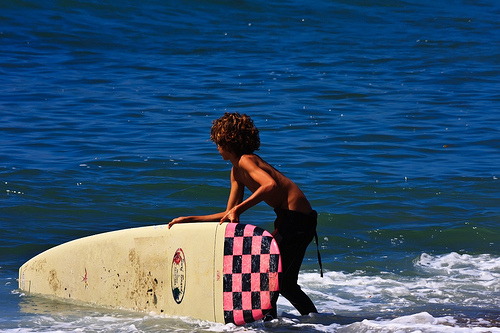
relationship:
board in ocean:
[18, 221, 285, 326] [0, 0, 500, 332]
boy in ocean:
[165, 111, 319, 325] [0, 0, 500, 332]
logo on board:
[168, 246, 187, 305] [18, 221, 285, 326]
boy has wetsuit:
[165, 111, 319, 325] [231, 151, 321, 309]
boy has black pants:
[165, 111, 319, 325] [264, 209, 326, 321]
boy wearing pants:
[165, 111, 319, 325] [259, 202, 322, 312]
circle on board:
[156, 247, 211, 302] [13, 210, 293, 323]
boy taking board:
[156, 99, 321, 320] [18, 221, 285, 326]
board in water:
[18, 221, 285, 326] [5, 3, 498, 324]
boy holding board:
[165, 111, 319, 325] [18, 221, 285, 326]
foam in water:
[286, 251, 483, 330] [318, 79, 481, 223]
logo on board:
[166, 242, 191, 306] [18, 221, 285, 326]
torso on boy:
[224, 156, 301, 211] [165, 111, 319, 325]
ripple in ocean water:
[374, 221, 439, 238] [16, 12, 206, 194]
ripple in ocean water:
[349, 194, 411, 216] [16, 12, 206, 194]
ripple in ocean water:
[342, 127, 422, 153] [16, 12, 206, 194]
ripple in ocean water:
[426, 65, 499, 92] [16, 12, 206, 194]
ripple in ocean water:
[283, 50, 339, 82] [16, 12, 206, 194]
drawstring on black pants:
[312, 230, 324, 275] [264, 209, 326, 321]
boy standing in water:
[165, 111, 319, 325] [309, 265, 419, 325]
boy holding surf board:
[165, 111, 319, 325] [16, 218, 281, 321]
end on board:
[222, 220, 282, 325] [18, 221, 285, 326]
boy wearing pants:
[165, 111, 319, 325] [269, 208, 324, 314]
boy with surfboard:
[156, 99, 321, 320] [17, 210, 288, 318]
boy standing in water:
[156, 99, 321, 320] [5, 3, 498, 324]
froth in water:
[339, 275, 434, 326] [5, 3, 498, 324]